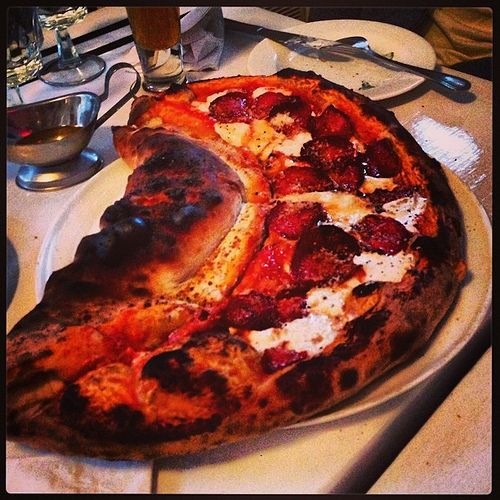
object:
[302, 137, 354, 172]
pepperoni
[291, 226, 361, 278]
pepperoni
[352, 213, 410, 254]
pepperoni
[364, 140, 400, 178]
pepperoni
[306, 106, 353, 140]
pepperoni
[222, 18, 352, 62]
knife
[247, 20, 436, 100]
plate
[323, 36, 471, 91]
fork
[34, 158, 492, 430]
dish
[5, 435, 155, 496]
napkin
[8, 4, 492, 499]
table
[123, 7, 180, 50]
beer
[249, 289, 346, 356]
cheese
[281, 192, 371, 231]
cheese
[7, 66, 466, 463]
pizza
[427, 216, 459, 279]
crust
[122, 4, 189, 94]
glass